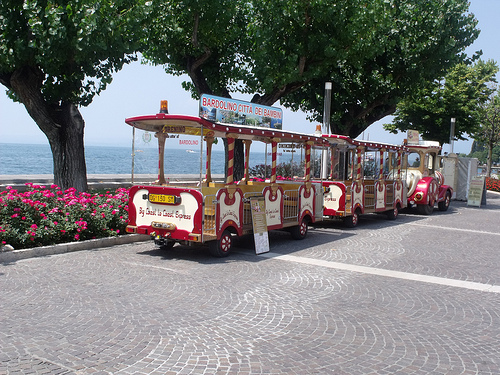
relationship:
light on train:
[156, 102, 173, 114] [172, 136, 278, 243]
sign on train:
[210, 89, 294, 128] [172, 136, 278, 243]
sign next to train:
[210, 89, 294, 128] [172, 136, 278, 243]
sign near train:
[210, 89, 294, 128] [172, 136, 278, 243]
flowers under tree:
[6, 186, 45, 204] [17, 123, 95, 144]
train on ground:
[172, 136, 278, 243] [59, 283, 148, 319]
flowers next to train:
[6, 186, 45, 204] [172, 136, 278, 243]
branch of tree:
[73, 82, 110, 114] [17, 123, 95, 144]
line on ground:
[320, 262, 325, 264] [59, 283, 148, 319]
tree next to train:
[17, 123, 95, 144] [172, 136, 278, 243]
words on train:
[191, 93, 233, 110] [172, 136, 278, 243]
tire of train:
[203, 232, 242, 254] [172, 136, 278, 243]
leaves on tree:
[76, 47, 90, 51] [17, 123, 95, 144]